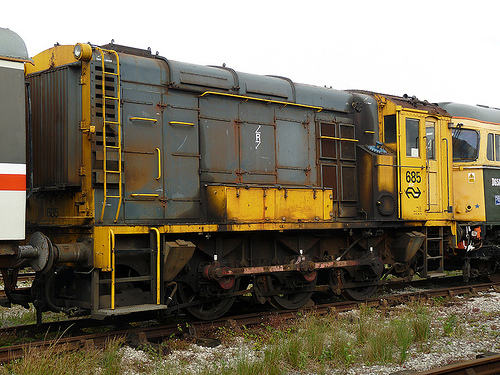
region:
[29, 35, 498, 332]
grey and yellow train parked on tracks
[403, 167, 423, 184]
685 printed on side of car in black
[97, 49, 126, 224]
yellow ladder on side of car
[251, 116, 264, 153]
white design printed on side of car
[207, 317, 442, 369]
patch of grass between tracks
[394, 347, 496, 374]
part of another train track in right corner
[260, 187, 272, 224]
rust on side of train car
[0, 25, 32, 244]
white red and grey train car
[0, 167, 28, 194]
red stripe on train car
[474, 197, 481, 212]
blue star printed on side of train car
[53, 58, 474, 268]
The train on the track.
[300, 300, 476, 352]
Grass and rocks between the tracks.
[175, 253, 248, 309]
Wheel of the train.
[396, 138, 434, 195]
The number 685 on the train.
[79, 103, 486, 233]
The train is yellow and black.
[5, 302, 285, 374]
The tracks look rusty.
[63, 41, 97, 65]
A light on top of the train car.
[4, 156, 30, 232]
Train car is orange and white.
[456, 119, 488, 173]
Window on the train.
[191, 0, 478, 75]
The sky is clear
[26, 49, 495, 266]
yellow and gray train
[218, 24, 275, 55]
white clouds in blue sky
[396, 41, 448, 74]
white clouds in blue sky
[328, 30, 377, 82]
white clouds in blue sky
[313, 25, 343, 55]
white clouds in blue sky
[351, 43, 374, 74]
white clouds in blue sky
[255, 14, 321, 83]
white clouds in blue sky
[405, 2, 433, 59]
white clouds in blue sky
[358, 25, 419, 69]
white clouds in blue sky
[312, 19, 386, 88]
white clouds in blue sky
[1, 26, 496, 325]
Train on the tracks.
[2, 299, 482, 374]
Grass growing in the gravel.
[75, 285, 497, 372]
Gravel beside the tracks.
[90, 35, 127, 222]
Yellow ladder on the train.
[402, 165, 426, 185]
number on the side of the train.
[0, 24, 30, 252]
Red, white, and gray colors on the train.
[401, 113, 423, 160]
Window on the train.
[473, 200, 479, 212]
star on the train.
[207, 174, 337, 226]
Yellow boxes on the train.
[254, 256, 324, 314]
Wheel on the train.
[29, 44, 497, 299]
gray and yelllow train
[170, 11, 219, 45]
white clouds in blue sky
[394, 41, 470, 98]
white clouds in blue sky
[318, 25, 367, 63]
white clouds in blue sky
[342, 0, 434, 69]
white clouds in blue sky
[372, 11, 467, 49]
white clouds in blue sky